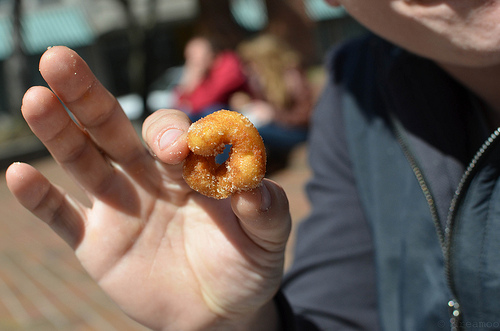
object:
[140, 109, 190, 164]
finger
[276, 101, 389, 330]
arm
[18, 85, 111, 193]
finger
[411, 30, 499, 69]
jaw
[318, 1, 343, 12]
ear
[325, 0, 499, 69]
face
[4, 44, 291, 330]
hand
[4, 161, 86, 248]
finger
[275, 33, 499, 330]
jacket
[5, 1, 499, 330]
man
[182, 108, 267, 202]
doughnut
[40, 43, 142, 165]
finger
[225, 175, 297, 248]
thumb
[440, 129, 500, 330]
zipper